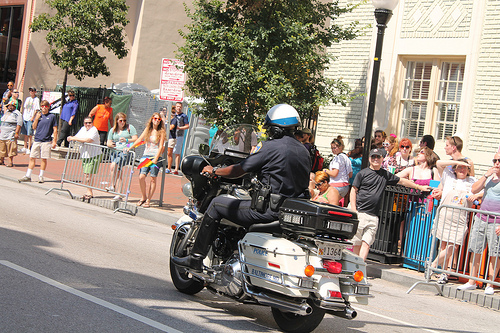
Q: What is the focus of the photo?
A: Motorcycle.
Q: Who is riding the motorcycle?
A: Police officer.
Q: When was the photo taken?
A: Daytime.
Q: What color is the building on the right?
A: White.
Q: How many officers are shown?
A: One.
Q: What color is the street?
A: Gray.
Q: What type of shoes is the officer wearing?
A: Boots.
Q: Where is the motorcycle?
A: Street.